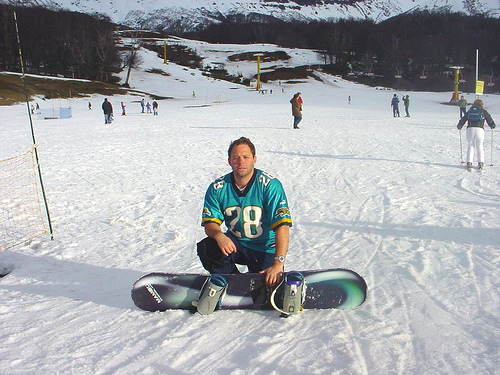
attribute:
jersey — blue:
[199, 168, 293, 260]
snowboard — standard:
[128, 269, 368, 311]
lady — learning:
[453, 93, 495, 173]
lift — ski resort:
[155, 38, 174, 63]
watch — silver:
[263, 250, 316, 272]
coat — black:
[455, 108, 495, 129]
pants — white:
[463, 129, 485, 165]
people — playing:
[55, 94, 182, 123]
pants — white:
[189, 225, 291, 286]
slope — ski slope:
[127, 25, 349, 114]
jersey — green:
[211, 168, 297, 251]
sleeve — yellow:
[270, 203, 293, 230]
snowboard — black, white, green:
[130, 264, 365, 311]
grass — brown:
[1, 71, 126, 107]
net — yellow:
[3, 135, 57, 263]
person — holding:
[289, 92, 302, 126]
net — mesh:
[31, 103, 76, 121]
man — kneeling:
[196, 145, 302, 301]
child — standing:
[121, 99, 134, 117]